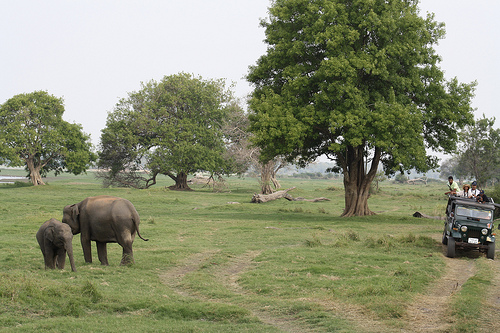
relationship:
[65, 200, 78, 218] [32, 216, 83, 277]
ear on elephant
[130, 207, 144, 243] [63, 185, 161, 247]
tail on elephant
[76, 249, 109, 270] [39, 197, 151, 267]
legs on elephant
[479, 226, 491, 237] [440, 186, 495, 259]
headlight on jeep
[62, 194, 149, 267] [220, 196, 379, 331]
elephant on grass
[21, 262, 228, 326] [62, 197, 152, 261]
grass beside elephant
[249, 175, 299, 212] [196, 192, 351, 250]
trunk on grass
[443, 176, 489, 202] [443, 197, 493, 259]
people leaning on truck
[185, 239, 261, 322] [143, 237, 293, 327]
marks in ground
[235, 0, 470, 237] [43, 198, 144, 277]
trees behind elephants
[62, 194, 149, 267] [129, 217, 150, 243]
elephant has curved tail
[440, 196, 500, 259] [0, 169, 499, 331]
jeep driving on grass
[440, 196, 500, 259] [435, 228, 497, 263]
jeep has wheels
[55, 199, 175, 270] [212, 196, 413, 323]
elephant on field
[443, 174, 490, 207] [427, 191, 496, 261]
people hanging out of jeep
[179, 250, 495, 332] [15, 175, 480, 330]
dirt path on ground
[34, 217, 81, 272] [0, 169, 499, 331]
elephant standing in grass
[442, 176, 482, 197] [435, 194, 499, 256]
men in truck